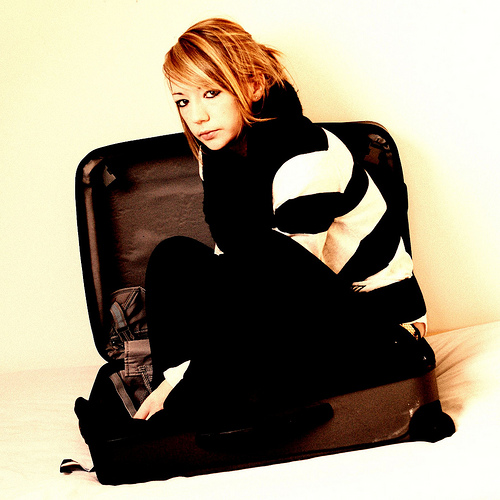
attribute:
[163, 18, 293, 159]
hair — light brown, blonde highlighted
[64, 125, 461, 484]
suitcase — grey, black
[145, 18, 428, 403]
person — sitting, adult female, looking, waiting, enjoying, awake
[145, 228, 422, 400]
pants — black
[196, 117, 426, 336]
sweater — black, white, striped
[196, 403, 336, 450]
handle — black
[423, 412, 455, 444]
wheel — black